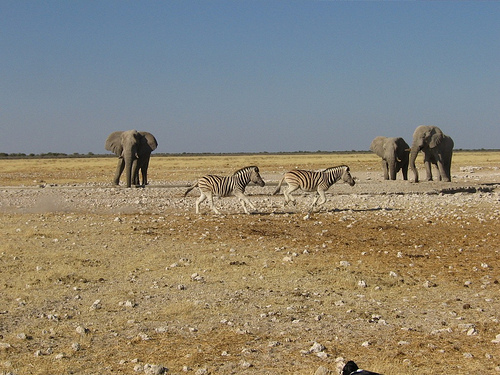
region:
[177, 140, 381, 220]
these two zebra are running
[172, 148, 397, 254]
two galloping zebras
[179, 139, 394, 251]
the zebras have black and brown stripes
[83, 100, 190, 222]
a large grey elephant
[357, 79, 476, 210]
two large elephants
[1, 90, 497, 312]
the animals are in a desert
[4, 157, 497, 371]
the ground looks very dry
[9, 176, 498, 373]
the ground is covered in rocks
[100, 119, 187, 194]
this elephant has tusks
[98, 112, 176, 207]
the elephant has large ears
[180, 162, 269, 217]
zebra running on a rocky dirt field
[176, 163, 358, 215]
two zebras running on rocky field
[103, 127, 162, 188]
an elephant standing on a rocky dirt field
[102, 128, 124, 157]
ear of an elephant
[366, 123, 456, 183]
two elephants on a rocky dirt field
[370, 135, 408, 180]
young elephant on a rocky field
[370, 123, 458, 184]
an adult elephant next to a baby elephant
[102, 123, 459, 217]
animals on a rocky dirt field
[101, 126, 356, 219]
two zebras and elephant on a rocky ground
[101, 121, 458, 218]
three elephants and two zebras on a rocky ground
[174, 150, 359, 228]
the zebras are running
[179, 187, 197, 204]
zebra's tail is black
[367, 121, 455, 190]
elephants standing next to each other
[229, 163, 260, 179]
zebra's mane hair is black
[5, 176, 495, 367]
rocks on the ground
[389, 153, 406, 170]
elephant's tusk is white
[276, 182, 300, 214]
zebra's legs in the air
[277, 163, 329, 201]
dirt on zebra's body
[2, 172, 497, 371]
the rocks are white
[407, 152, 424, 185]
elephant's trunk touching the ground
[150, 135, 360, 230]
the zebras are black and white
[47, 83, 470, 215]
the elephants are standing outside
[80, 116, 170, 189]
the elephant is facing the camera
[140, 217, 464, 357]
rocks on the ground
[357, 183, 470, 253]
the rocks are white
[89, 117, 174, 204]
the elephant is big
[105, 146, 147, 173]
the elephant has tusks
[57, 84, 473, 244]
the animals are free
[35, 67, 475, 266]
the animals are in the wild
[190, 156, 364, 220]
zebras on the rocks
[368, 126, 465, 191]
elephants on the rocks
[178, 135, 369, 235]
zebra is chasing a zebra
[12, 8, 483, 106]
the sky is blue and clear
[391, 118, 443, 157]
elephant with tusks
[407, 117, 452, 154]
head of the elephant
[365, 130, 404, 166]
the head of the elephant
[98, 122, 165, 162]
the head of the elephant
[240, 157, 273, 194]
the head of the zebra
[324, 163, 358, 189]
the head of the zebra